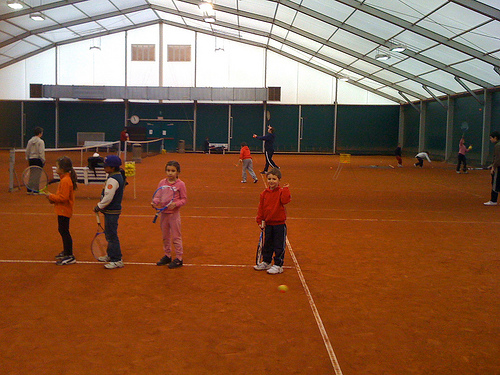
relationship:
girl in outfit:
[148, 159, 199, 272] [149, 170, 189, 258]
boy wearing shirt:
[255, 166, 290, 275] [256, 178, 292, 224]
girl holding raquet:
[138, 152, 197, 281] [148, 176, 171, 223]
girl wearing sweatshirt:
[35, 153, 85, 268] [38, 173, 83, 218]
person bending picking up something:
[413, 144, 453, 177] [426, 162, 434, 167]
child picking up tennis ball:
[412, 150, 433, 169] [275, 282, 292, 292]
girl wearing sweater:
[151, 160, 188, 268] [150, 175, 188, 212]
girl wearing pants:
[151, 160, 188, 268] [159, 212, 183, 260]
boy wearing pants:
[255, 166, 290, 275] [263, 222, 285, 264]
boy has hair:
[252, 170, 291, 273] [267, 168, 282, 176]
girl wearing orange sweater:
[35, 153, 85, 268] [41, 172, 78, 224]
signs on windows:
[122, 37, 207, 67] [2, 2, 497, 115]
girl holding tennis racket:
[147, 155, 194, 272] [146, 179, 180, 222]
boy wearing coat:
[252, 170, 291, 273] [253, 187, 291, 224]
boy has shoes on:
[255, 166, 290, 275] [250, 252, 285, 278]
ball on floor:
[273, 279, 289, 294] [0, 148, 499, 372]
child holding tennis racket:
[251, 170, 293, 277] [255, 219, 263, 264]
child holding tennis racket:
[151, 159, 188, 267] [150, 184, 176, 226]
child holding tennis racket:
[94, 156, 128, 269] [90, 208, 107, 263]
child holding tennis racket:
[38, 158, 75, 264] [20, 164, 50, 195]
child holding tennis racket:
[235, 141, 257, 184] [20, 164, 50, 195]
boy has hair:
[255, 166, 290, 275] [262, 164, 282, 184]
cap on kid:
[97, 157, 127, 170] [92, 155, 126, 270]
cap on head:
[97, 157, 127, 170] [99, 154, 121, 176]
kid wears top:
[413, 146, 427, 168] [417, 149, 429, 160]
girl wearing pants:
[137, 154, 201, 269] [147, 210, 194, 262]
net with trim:
[121, 135, 167, 166] [124, 134, 162, 147]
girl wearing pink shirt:
[147, 155, 194, 272] [152, 176, 189, 243]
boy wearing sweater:
[255, 166, 290, 275] [252, 187, 324, 232]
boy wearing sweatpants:
[255, 166, 290, 275] [246, 211, 313, 263]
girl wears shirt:
[151, 160, 188, 268] [151, 175, 186, 212]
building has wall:
[0, 0, 497, 372] [1, 102, 406, 152]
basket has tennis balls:
[123, 160, 137, 200] [123, 160, 135, 175]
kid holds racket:
[256, 170, 292, 276] [256, 220, 265, 263]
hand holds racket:
[256, 214, 266, 229] [256, 220, 265, 263]